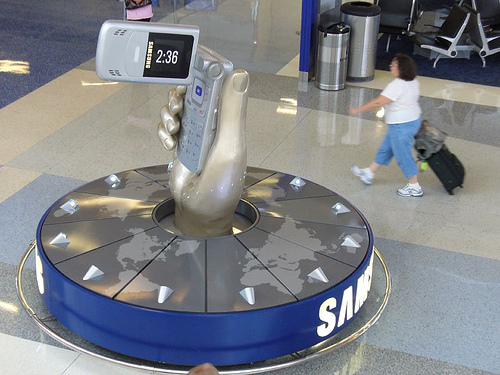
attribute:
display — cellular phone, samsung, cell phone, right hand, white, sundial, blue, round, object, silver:
[19, 18, 393, 371]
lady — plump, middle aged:
[344, 52, 426, 202]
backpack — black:
[416, 117, 466, 198]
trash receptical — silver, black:
[338, 1, 380, 83]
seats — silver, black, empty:
[413, 2, 499, 71]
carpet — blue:
[3, 1, 99, 100]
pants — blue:
[377, 115, 421, 181]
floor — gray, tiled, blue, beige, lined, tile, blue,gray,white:
[7, 79, 170, 199]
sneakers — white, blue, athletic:
[350, 165, 427, 200]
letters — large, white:
[144, 38, 155, 71]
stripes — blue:
[399, 187, 424, 192]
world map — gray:
[72, 169, 366, 307]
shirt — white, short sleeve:
[382, 78, 421, 125]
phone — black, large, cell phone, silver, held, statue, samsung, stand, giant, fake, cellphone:
[93, 17, 235, 177]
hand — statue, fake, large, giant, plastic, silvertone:
[157, 69, 251, 238]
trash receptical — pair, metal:
[312, 0, 386, 94]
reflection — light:
[267, 86, 304, 122]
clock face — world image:
[143, 32, 188, 79]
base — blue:
[35, 219, 377, 367]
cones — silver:
[154, 281, 267, 312]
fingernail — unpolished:
[229, 73, 251, 95]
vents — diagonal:
[108, 27, 134, 77]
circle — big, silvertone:
[16, 237, 392, 374]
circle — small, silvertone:
[148, 197, 262, 242]